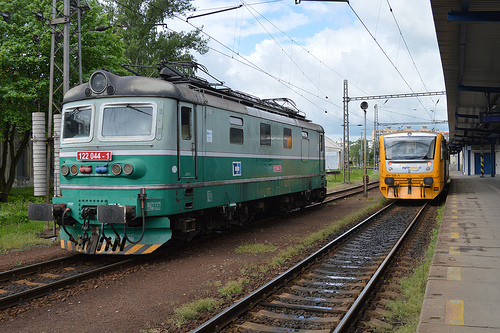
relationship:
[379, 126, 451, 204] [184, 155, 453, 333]
train on a track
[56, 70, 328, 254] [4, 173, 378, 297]
train on a track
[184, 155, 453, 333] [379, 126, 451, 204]
track under train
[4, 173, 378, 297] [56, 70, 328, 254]
track under train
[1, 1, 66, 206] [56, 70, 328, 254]
tree next to train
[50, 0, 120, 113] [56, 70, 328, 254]
tree next to train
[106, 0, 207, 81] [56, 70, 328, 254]
tree next to train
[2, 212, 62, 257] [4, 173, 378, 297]
grass near track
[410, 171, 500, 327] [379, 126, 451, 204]
platform for train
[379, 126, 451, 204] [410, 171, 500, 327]
train near platform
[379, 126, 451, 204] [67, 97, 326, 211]
train color aqua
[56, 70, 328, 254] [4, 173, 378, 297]
train on track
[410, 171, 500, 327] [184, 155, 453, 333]
platform next to track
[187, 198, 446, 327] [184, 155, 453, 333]
metal train track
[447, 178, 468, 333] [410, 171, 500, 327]
lines on platform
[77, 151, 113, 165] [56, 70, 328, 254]
plate on train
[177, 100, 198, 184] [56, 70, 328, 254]
door on train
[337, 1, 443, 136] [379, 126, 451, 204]
wire above train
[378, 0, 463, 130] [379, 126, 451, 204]
wire above train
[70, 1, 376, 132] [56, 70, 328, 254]
wire above train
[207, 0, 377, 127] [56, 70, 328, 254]
wire above train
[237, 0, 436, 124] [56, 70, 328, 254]
wire above train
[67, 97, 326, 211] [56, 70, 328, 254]
blue on train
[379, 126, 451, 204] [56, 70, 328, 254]
train by a train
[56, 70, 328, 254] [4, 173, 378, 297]
train on tracks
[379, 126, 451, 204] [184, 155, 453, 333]
train on tracks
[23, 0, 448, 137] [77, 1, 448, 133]
clouds in sky